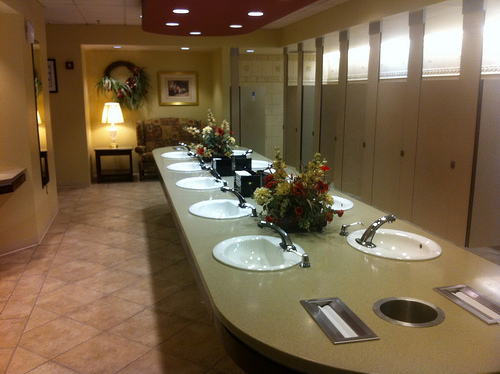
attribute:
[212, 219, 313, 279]
sink — white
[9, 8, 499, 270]
bathroom — public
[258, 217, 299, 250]
tap — metallic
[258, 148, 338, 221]
flower — arranged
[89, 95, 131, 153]
lamp — lit, bright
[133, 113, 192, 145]
couch — comfy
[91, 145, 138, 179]
table — wooden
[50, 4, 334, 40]
ceiling — red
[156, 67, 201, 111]
frame — gold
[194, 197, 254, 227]
sink — white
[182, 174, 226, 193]
sink — white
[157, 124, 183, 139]
patterns — floral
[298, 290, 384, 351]
dispenser — silver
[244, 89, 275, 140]
door — open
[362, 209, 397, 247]
faucet — curved